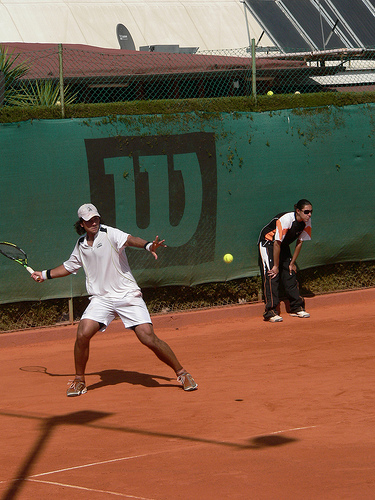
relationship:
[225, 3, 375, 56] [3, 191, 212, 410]
panel behind man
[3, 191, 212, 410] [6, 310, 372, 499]
man on court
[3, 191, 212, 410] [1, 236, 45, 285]
man holding racket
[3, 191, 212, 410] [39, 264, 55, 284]
man wearing wristband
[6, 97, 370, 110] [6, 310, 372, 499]
grass behind court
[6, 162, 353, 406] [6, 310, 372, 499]
people on court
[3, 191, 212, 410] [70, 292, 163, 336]
man in shorts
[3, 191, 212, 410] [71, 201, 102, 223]
man wearing cap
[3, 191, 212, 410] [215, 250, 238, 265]
man hitting ball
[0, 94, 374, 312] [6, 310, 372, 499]
screen behind court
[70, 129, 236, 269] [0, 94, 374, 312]
logo on screen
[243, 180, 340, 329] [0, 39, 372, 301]
person leaning on fence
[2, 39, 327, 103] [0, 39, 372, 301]
building behind fence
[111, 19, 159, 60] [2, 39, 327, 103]
dish on building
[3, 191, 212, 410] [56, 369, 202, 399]
man wearing shoes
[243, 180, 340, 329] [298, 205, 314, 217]
person in glasses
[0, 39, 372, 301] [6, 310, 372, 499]
fence near court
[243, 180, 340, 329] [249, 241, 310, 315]
person in pants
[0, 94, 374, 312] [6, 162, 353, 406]
screen behind people